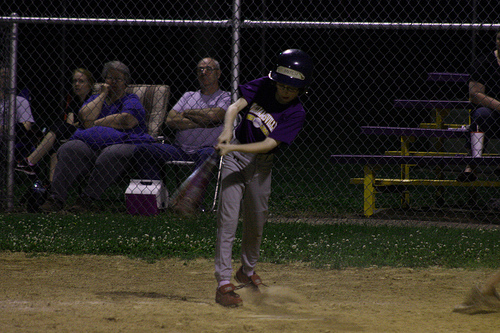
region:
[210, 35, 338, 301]
boy hitting a ball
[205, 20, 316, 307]
boy wearing a blue helmet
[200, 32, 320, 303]
boy wearing a blue uniform shirt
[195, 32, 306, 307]
boy wearing gray uiform pants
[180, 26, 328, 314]
boy holding a bat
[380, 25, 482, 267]
bleachers next to a fence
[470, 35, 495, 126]
man sitting on bleachers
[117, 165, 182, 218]
cooler sitting on grass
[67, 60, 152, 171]
woman sittingin a chair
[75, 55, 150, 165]
woman wearing a purple shirt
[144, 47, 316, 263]
a young boy swinging a bat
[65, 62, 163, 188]
a woman sitting in a chair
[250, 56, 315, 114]
a young boy wearing a helmet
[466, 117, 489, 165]
a white plastic cup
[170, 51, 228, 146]
a man with his arms crossed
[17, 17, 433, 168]
a chain link fence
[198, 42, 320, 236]
a young boy holding a bat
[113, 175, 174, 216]
a red and white cooler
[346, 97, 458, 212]
purple and yellow bleachers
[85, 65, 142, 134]
a woman wearing glasses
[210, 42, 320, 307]
batter swinging a black bat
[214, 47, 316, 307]
batter wearing a purple shirt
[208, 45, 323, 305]
batter wearing red shoes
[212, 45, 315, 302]
batter wearing grey pants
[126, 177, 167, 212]
small cooler sitting in grass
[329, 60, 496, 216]
purple and yellow bleachers behind fence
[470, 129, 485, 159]
tal white cup sitting on bleachers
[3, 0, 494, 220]
tall fence posted behind the batter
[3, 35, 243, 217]
people sitting behind the fence watching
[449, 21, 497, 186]
person sitting on bleachers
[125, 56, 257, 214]
a player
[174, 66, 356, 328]
a player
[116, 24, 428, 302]
a player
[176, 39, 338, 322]
a boy swinging a bat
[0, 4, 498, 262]
a fence behind the boy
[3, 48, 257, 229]
people are watching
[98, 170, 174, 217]
the cooler is purple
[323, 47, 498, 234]
the bleachers are purple and yellow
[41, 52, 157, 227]
the older woman is wearing a blue shirt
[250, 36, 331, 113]
the boy is wearing a helmet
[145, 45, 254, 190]
the man has his arms crossed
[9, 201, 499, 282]
the grass has little white flowers in it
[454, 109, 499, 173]
a cup is on the bleachers